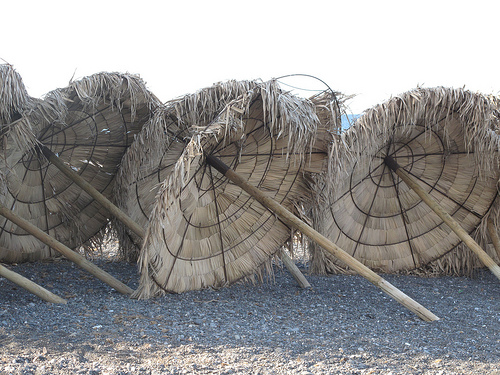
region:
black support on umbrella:
[392, 173, 422, 267]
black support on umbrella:
[402, 165, 481, 221]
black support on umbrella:
[395, 145, 489, 165]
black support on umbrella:
[394, 110, 455, 157]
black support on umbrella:
[332, 161, 384, 214]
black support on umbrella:
[355, 166, 390, 258]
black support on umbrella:
[208, 171, 240, 279]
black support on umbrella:
[169, 174, 213, 284]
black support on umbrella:
[211, 145, 321, 162]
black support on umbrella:
[220, 117, 272, 157]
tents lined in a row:
[5, 45, 494, 330]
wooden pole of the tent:
[241, 173, 440, 323]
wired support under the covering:
[191, 136, 283, 240]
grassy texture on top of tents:
[273, 85, 318, 157]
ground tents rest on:
[21, 270, 471, 344]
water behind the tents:
[346, 103, 362, 133]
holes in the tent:
[73, 150, 110, 178]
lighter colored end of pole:
[383, 282, 439, 322]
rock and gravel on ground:
[236, 304, 318, 349]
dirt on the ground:
[30, 265, 97, 304]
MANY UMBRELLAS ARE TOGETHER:
[1, 43, 497, 328]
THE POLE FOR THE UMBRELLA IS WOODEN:
[200, 151, 440, 343]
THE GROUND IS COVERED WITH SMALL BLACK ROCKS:
[0, 255, 496, 372]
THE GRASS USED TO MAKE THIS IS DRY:
[110, 93, 355, 308]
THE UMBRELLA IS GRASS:
[100, 80, 360, 326]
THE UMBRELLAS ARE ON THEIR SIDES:
[0, 60, 497, 312]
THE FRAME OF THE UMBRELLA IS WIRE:
[183, 112, 283, 209]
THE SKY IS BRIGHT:
[1, 0, 496, 150]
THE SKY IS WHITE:
[1, 3, 499, 130]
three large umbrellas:
[19, 78, 454, 308]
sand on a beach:
[96, 282, 438, 366]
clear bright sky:
[93, 10, 360, 62]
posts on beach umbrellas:
[227, 155, 470, 352]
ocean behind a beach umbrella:
[312, 93, 382, 143]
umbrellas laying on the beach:
[26, 70, 446, 292]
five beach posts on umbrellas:
[9, 98, 481, 322]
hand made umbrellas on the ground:
[36, 61, 441, 265]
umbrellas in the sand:
[44, 77, 464, 321]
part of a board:
[413, 295, 426, 323]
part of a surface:
[313, 267, 318, 280]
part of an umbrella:
[423, 243, 424, 253]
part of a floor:
[297, 315, 306, 328]